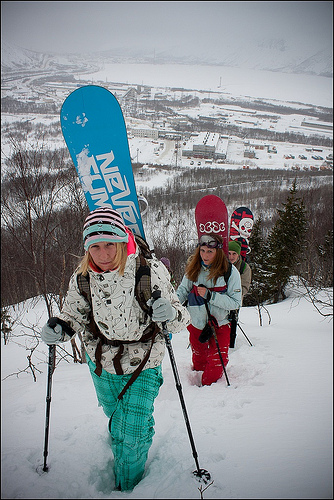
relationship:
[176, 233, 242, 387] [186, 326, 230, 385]
girl has red snowpants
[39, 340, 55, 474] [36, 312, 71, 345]
pole in hand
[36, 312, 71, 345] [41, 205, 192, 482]
hand of girl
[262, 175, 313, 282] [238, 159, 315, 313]
pine tree in distance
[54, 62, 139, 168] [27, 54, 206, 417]
top of a snowboard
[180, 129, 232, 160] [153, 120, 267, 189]
building in a distance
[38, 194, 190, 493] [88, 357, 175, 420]
girl wearing green snowpants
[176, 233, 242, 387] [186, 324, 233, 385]
girl wearing red snowpants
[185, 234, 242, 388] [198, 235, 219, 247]
girl wearing goggles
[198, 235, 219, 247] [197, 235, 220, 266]
goggles on her head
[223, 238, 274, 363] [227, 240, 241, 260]
person wearing green hat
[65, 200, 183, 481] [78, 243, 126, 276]
girl with blonde hair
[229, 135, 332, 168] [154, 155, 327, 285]
parking lot of hill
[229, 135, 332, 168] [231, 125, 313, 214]
parking lot at bottom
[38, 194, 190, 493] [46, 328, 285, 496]
girl walking in snow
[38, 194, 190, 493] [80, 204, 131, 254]
girl has cap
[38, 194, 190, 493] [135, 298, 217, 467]
girl has pole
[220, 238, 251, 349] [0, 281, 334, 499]
person on hill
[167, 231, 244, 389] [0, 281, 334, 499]
person on hill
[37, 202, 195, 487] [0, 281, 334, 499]
person on hill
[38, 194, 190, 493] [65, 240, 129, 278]
girl has blonde hair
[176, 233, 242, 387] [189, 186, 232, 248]
girl has snowboard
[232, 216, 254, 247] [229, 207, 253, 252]
skull design on snowboard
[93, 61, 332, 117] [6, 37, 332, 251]
snow on ground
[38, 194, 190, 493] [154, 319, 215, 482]
girl has ski pole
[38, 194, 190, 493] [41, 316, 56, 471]
girl has pole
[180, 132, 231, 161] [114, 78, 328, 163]
building on distance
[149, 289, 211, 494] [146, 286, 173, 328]
ski pole in hand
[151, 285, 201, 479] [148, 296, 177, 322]
ski pole in hand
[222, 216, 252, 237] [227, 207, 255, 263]
skull in snowboard